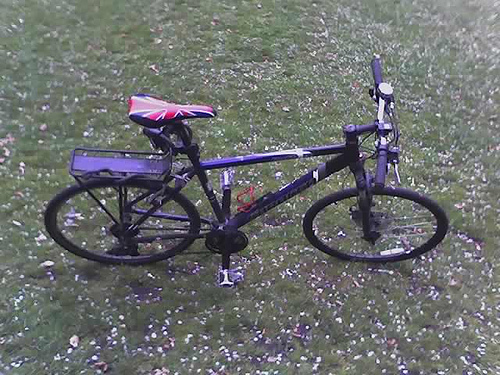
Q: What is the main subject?
A: Bicycle.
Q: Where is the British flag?
A: On the seat.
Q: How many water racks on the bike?
A: One.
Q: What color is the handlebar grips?
A: Purple.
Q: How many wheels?
A: Two.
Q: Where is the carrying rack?
A: Behind the seat.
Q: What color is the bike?
A: Purple.